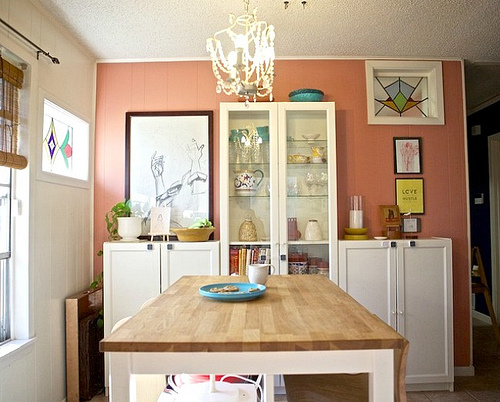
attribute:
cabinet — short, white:
[337, 234, 454, 391]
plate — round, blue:
[198, 281, 269, 301]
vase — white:
[112, 210, 149, 244]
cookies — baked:
[206, 282, 256, 294]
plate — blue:
[196, 276, 266, 301]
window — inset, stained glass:
[34, 91, 99, 196]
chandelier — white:
[203, 0, 277, 106]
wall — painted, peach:
[97, 62, 122, 203]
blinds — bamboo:
[0, 57, 27, 170]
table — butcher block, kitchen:
[161, 251, 395, 393]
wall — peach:
[91, 59, 475, 376]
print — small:
[392, 177, 424, 217]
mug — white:
[243, 259, 277, 288]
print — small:
[393, 138, 423, 175]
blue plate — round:
[196, 280, 276, 305]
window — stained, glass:
[42, 100, 94, 180]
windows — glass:
[227, 109, 330, 277]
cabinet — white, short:
[100, 237, 220, 391]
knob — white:
[399, 307, 411, 316]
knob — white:
[389, 307, 398, 316]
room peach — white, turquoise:
[91, 62, 468, 233]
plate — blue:
[175, 242, 287, 309]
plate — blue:
[242, 277, 247, 289]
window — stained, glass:
[40, 99, 89, 181]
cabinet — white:
[101, 240, 159, 333]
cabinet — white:
[160, 242, 219, 283]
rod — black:
[0, 17, 58, 63]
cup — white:
[245, 261, 277, 285]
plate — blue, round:
[197, 279, 266, 301]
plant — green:
[96, 193, 146, 213]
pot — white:
[111, 191, 169, 239]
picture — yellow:
[394, 177, 427, 217]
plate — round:
[191, 249, 270, 313]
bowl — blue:
[210, 262, 274, 319]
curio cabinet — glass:
[206, 92, 346, 289]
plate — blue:
[197, 273, 271, 303]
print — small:
[392, 130, 424, 177]